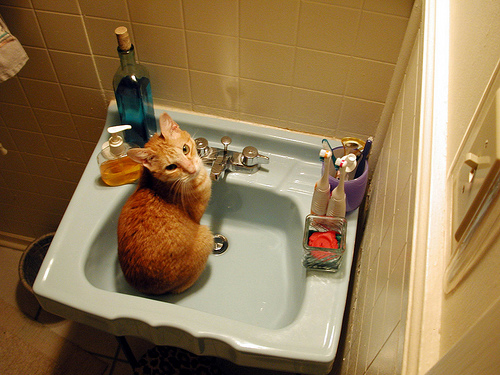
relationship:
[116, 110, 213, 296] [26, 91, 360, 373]
cat sitting in bathroom sink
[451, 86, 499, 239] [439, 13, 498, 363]
light switch on wall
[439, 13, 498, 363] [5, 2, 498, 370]
wall in bathroom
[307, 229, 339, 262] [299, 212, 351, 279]
candle in holder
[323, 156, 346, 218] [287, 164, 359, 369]
brush standing on sink ledge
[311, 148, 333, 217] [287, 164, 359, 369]
brush standing on sink ledge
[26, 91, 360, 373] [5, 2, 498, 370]
bathroom sink in bathroom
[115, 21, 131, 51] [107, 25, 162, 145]
cork in bottle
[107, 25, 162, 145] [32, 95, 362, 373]
bottle resting on sink ledge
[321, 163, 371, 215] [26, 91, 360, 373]
purple cup on bathroom sink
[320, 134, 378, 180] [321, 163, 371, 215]
toiletries in purple cup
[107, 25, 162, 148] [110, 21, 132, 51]
bottle on cork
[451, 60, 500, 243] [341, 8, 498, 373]
light switch on wall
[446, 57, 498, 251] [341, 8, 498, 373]
light switch on wall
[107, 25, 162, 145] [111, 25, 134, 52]
bottle on cork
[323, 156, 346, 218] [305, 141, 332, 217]
brush on brush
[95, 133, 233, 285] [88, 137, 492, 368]
cat on sink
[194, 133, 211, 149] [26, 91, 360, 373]
knob on bathroom sink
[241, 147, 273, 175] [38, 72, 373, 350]
knob on sink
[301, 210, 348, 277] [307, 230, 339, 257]
candle holder with candle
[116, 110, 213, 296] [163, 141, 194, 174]
cat has eyes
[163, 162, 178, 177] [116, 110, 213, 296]
eye of cat